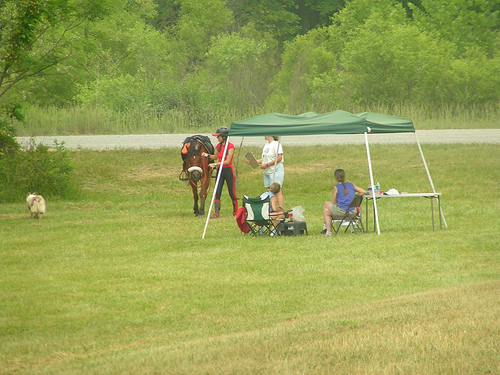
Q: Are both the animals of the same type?
A: No, they are horses and dogs.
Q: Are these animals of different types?
A: Yes, they are horses and dogs.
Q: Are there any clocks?
A: No, there are no clocks.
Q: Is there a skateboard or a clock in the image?
A: No, there are no clocks or skateboards.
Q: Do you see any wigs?
A: No, there are no wigs.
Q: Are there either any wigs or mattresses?
A: No, there are no wigs or mattresses.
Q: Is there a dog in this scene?
A: Yes, there is a dog.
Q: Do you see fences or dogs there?
A: Yes, there is a dog.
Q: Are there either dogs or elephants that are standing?
A: Yes, the dog is standing.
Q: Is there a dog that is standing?
A: Yes, there is a dog that is standing.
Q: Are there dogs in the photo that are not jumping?
A: Yes, there is a dog that is standing.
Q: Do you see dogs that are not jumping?
A: Yes, there is a dog that is standing .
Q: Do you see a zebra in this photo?
A: No, there are no zebras.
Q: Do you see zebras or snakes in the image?
A: No, there are no zebras or snakes.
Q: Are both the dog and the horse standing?
A: Yes, both the dog and the horse are standing.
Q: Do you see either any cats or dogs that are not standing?
A: No, there is a dog but it is standing.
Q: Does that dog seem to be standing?
A: Yes, the dog is standing.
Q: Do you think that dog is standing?
A: Yes, the dog is standing.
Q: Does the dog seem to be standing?
A: Yes, the dog is standing.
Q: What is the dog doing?
A: The dog is standing.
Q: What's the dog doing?
A: The dog is standing.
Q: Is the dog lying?
A: No, the dog is standing.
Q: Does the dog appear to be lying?
A: No, the dog is standing.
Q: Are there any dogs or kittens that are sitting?
A: No, there is a dog but it is standing.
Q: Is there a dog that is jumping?
A: No, there is a dog but it is standing.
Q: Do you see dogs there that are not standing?
A: No, there is a dog but it is standing.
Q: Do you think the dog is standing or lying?
A: The dog is standing.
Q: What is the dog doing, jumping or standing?
A: The dog is standing.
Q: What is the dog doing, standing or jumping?
A: The dog is standing.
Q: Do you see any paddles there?
A: No, there are no paddles.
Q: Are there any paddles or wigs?
A: No, there are no paddles or wigs.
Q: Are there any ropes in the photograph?
A: No, there are no ropes.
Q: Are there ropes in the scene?
A: No, there are no ropes.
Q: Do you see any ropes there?
A: No, there are no ropes.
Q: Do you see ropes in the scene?
A: No, there are no ropes.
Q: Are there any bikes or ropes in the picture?
A: No, there are no ropes or bikes.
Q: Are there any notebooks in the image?
A: No, there are no notebooks.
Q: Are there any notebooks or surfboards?
A: No, there are no notebooks or surfboards.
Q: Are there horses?
A: Yes, there is a horse.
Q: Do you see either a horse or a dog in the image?
A: Yes, there is a horse.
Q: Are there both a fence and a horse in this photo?
A: No, there is a horse but no fences.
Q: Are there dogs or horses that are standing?
A: Yes, the horse is standing.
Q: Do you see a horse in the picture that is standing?
A: Yes, there is a horse that is standing.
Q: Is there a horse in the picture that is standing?
A: Yes, there is a horse that is standing.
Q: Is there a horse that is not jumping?
A: Yes, there is a horse that is standing.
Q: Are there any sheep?
A: No, there are no sheep.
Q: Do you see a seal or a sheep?
A: No, there are no sheep or seals.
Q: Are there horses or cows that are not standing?
A: No, there is a horse but it is standing.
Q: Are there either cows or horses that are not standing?
A: No, there is a horse but it is standing.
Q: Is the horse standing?
A: Yes, the horse is standing.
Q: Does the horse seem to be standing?
A: Yes, the horse is standing.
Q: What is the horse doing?
A: The horse is standing.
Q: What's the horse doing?
A: The horse is standing.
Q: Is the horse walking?
A: No, the horse is standing.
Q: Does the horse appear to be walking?
A: No, the horse is standing.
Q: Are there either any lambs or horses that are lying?
A: No, there is a horse but it is standing.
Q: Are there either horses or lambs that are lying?
A: No, there is a horse but it is standing.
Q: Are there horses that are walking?
A: No, there is a horse but it is standing.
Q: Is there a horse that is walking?
A: No, there is a horse but it is standing.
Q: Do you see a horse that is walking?
A: No, there is a horse but it is standing.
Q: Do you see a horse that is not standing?
A: No, there is a horse but it is standing.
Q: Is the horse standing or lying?
A: The horse is standing.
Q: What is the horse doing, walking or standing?
A: The horse is standing.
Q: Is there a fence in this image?
A: No, there are no fences.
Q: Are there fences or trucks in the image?
A: No, there are no fences or trucks.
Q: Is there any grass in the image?
A: Yes, there is grass.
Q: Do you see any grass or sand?
A: Yes, there is grass.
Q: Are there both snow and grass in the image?
A: No, there is grass but no snow.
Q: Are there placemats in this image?
A: No, there are no placemats.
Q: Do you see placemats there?
A: No, there are no placemats.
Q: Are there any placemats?
A: No, there are no placemats.